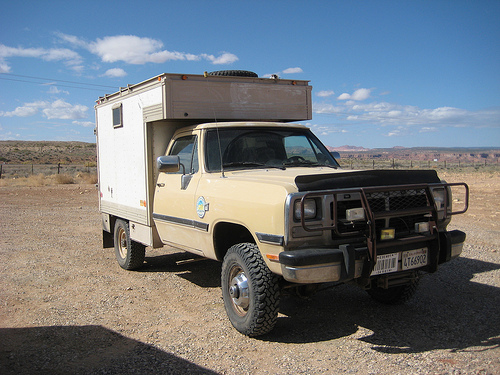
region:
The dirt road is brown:
[22, 265, 147, 365]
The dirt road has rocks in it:
[44, 310, 229, 373]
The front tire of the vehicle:
[219, 238, 279, 340]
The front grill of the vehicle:
[291, 173, 482, 286]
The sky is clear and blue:
[196, 9, 479, 52]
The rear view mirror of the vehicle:
[154, 151, 186, 178]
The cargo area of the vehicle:
[80, 63, 326, 241]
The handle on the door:
[148, 175, 174, 191]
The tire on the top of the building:
[195, 60, 267, 83]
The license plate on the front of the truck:
[351, 239, 443, 281]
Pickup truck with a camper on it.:
[86, 53, 470, 352]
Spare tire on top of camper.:
[203, 63, 264, 85]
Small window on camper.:
[105, 105, 131, 134]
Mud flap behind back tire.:
[91, 215, 130, 252]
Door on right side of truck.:
[158, 132, 213, 257]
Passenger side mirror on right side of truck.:
[151, 143, 190, 182]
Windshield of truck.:
[196, 128, 341, 172]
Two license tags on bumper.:
[362, 241, 440, 280]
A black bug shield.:
[287, 161, 449, 193]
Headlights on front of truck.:
[296, 180, 466, 224]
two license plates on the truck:
[370, 248, 429, 274]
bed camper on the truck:
[95, 75, 310, 246]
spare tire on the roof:
[205, 70, 260, 80]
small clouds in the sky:
[0, 28, 498, 145]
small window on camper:
[110, 101, 123, 128]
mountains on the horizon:
[0, 138, 498, 150]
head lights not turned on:
[292, 183, 452, 220]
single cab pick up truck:
[94, 68, 466, 335]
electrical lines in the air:
[4, 68, 126, 96]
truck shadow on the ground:
[133, 233, 497, 351]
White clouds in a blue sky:
[1, 2, 496, 147]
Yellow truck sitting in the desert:
[91, 71, 470, 335]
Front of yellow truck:
[283, 173, 467, 285]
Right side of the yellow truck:
[151, 122, 283, 275]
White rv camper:
[95, 73, 312, 226]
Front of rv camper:
[162, 70, 314, 122]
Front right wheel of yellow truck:
[220, 240, 278, 337]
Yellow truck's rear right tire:
[108, 215, 143, 270]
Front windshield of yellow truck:
[205, 125, 346, 171]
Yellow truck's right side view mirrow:
[154, 154, 180, 174]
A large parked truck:
[76, 74, 473, 331]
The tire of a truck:
[216, 240, 278, 335]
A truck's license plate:
[357, 248, 434, 275]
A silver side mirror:
[153, 151, 188, 183]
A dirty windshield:
[200, 130, 325, 172]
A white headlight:
[288, 193, 321, 222]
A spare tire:
[201, 67, 259, 81]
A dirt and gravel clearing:
[4, 182, 497, 372]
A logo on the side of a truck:
[191, 197, 213, 220]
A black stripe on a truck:
[151, 205, 220, 233]